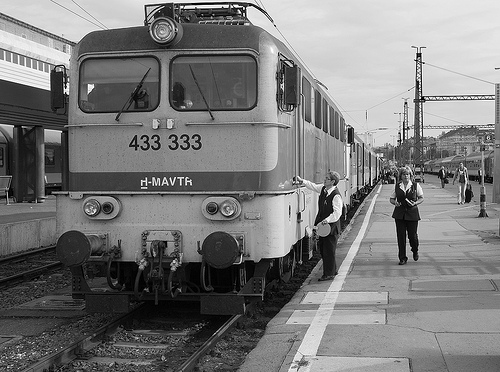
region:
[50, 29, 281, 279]
front of train on tracks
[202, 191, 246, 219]
lights on front of train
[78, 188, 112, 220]
lights on front of train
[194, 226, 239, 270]
front safety ram on train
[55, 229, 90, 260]
safety ram on train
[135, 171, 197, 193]
white writing on front of train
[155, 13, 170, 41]
light on top of train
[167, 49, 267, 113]
front window on train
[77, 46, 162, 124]
front window on train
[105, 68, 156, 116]
black window wiper on train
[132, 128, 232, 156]
black numbers on train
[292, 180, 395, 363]
white line on platform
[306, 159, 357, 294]
woman next to train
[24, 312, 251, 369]
train on black track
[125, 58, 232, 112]
windshield wipers on train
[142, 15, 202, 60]
white light on train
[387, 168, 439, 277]
woman walking on sidewalk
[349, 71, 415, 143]
power lines over train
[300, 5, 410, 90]
grey and cloudy sky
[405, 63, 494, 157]
black metal frame for power lines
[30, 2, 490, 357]
the picture is black and white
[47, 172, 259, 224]
the headlights are off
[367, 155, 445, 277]
a woman is in motion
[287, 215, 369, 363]
a white line on the edge of the platform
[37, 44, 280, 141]
the conductors car is empty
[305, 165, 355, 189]
the woman is wearing glasses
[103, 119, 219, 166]
the numbers on the train are black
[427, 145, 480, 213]
people walking on the platform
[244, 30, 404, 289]
the train has passengers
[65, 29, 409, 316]
the train is parked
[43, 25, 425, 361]
The photo is black and white.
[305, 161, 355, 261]
A lady next to the train.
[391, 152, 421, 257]
A woman standing on the platform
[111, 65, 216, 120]
Wipers on the windshield of the plane.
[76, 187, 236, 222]
headlight in front of the train.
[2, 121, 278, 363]
The train is on the tracks.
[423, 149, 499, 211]
People are walking on the sidewalk.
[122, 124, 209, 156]
Numbers in front of the train.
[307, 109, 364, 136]
Windows on the train.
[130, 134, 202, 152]
433 333 on the front of a bus.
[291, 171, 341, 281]
A man with short hair and glasses touching a train.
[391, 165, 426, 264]
A wonan with light hair with a large white collar walking this way.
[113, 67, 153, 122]
A black windshield wiper to the left of another.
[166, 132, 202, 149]
Black 333 after 433.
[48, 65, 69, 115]
Black back of a rear view mirror on the left.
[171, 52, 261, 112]
Front train windshield with the thinner wiper.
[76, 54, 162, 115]
Left windshield of a train.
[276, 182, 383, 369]
Long white line on a walkway.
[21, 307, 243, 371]
Brown shiny metal tracks in front of a train.